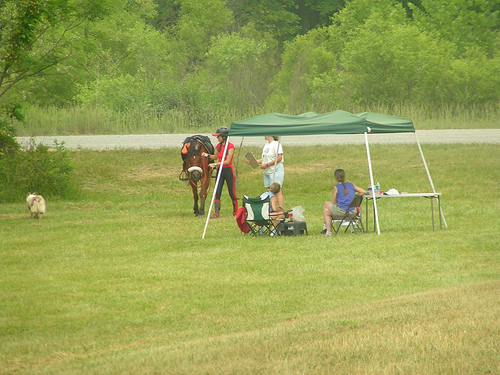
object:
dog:
[25, 193, 45, 217]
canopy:
[257, 117, 363, 127]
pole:
[366, 132, 387, 239]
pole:
[413, 133, 453, 224]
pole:
[269, 137, 283, 186]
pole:
[200, 138, 229, 239]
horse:
[176, 133, 213, 212]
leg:
[201, 176, 205, 221]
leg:
[193, 182, 198, 213]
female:
[212, 130, 231, 165]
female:
[259, 133, 278, 168]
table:
[366, 191, 441, 196]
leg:
[437, 196, 443, 227]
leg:
[430, 198, 434, 226]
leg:
[366, 200, 369, 230]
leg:
[372, 205, 376, 233]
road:
[81, 131, 152, 150]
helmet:
[218, 128, 224, 136]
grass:
[99, 202, 163, 243]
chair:
[351, 201, 361, 209]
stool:
[283, 223, 303, 233]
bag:
[294, 208, 302, 221]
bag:
[390, 190, 395, 195]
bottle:
[377, 184, 381, 193]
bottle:
[367, 185, 371, 195]